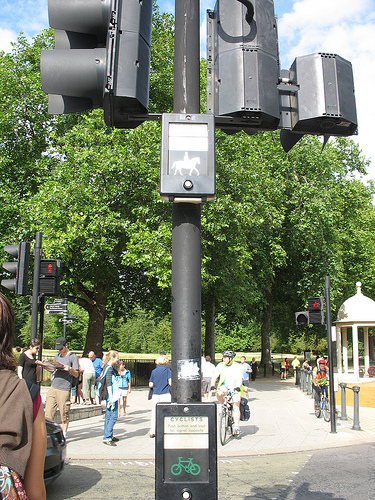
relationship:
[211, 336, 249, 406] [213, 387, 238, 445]
man riding a bike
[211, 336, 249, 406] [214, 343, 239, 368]
man wearing a helmet